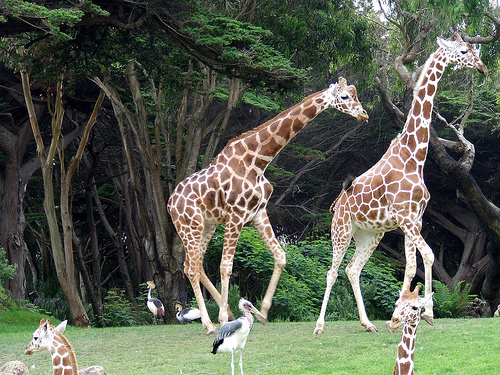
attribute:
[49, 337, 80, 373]
neck — light brown, white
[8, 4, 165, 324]
trees — green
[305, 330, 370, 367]
grass — green